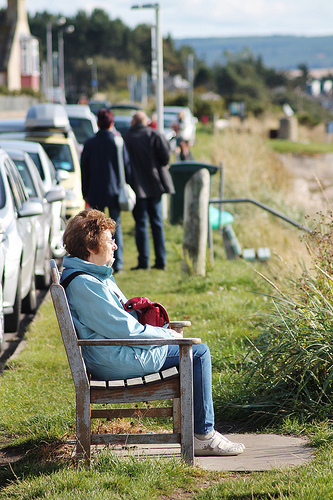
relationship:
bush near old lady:
[231, 269, 326, 421] [57, 206, 247, 458]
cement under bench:
[77, 383, 321, 483] [43, 254, 203, 465]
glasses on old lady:
[98, 235, 116, 245] [57, 206, 247, 458]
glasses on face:
[98, 235, 116, 245] [101, 233, 119, 267]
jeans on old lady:
[162, 341, 212, 434] [57, 206, 247, 458]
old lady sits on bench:
[57, 206, 247, 458] [43, 254, 203, 465]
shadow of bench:
[6, 432, 62, 485] [43, 254, 203, 465]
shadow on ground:
[6, 432, 62, 485] [5, 359, 324, 498]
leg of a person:
[150, 197, 168, 275] [122, 109, 177, 270]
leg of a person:
[165, 340, 245, 456] [58, 208, 245, 456]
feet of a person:
[193, 428, 243, 454] [58, 208, 245, 456]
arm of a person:
[68, 274, 185, 341] [58, 208, 245, 456]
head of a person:
[57, 207, 124, 268] [58, 208, 245, 456]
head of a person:
[126, 113, 153, 134] [124, 109, 172, 263]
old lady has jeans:
[57, 206, 247, 458] [162, 341, 216, 434]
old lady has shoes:
[57, 206, 247, 458] [174, 416, 262, 455]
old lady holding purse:
[57, 206, 247, 458] [123, 294, 172, 328]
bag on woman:
[89, 270, 197, 338] [60, 178, 261, 427]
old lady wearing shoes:
[57, 206, 247, 457] [194, 430, 246, 455]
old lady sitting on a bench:
[57, 206, 247, 458] [35, 260, 207, 469]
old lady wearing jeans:
[57, 206, 247, 458] [162, 341, 216, 434]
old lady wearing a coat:
[57, 206, 247, 458] [60, 255, 170, 381]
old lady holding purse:
[57, 206, 247, 458] [123, 284, 179, 338]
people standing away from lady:
[75, 105, 175, 274] [172, 107, 194, 158]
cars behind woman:
[3, 113, 66, 319] [47, 216, 226, 430]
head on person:
[65, 207, 119, 268] [58, 208, 245, 456]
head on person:
[92, 108, 118, 134] [81, 107, 128, 271]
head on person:
[132, 111, 150, 133] [122, 109, 169, 270]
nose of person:
[96, 237, 120, 253] [58, 208, 245, 456]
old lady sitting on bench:
[57, 206, 247, 458] [46, 281, 200, 473]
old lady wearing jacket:
[57, 206, 247, 458] [58, 253, 179, 380]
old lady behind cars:
[57, 206, 247, 458] [4, 138, 64, 259]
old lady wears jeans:
[57, 206, 247, 458] [109, 196, 182, 271]